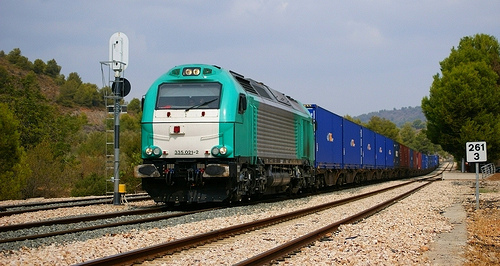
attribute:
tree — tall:
[420, 33, 499, 173]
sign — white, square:
[462, 134, 487, 166]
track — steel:
[2, 189, 154, 214]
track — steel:
[1, 205, 203, 242]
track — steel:
[80, 159, 456, 263]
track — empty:
[5, 193, 415, 264]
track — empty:
[367, 167, 462, 201]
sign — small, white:
[464, 140, 488, 170]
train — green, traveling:
[136, 61, 444, 208]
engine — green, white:
[109, 67, 321, 211]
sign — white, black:
[426, 134, 498, 168]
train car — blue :
[309, 101, 368, 189]